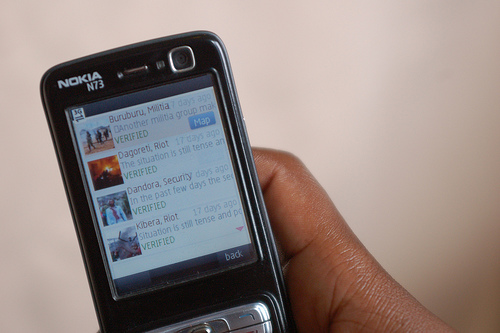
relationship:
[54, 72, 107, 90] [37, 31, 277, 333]
nokia written on cell phone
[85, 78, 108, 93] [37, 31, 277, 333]
n73 written on cell phone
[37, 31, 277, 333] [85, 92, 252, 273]
cell phone has a screen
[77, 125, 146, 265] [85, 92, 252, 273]
pictures are on screen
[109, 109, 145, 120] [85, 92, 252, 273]
buruburu written on screen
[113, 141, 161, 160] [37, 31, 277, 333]
dagoreti written on cell phone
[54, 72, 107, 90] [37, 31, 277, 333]
nokia n73 written on cell phone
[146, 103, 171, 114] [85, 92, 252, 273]
militia written on screen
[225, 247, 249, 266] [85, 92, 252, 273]
word written on screen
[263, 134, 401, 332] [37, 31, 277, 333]
person holding cell phone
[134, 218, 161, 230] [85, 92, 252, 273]
kibera written on screen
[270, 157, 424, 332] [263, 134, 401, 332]
hand of a person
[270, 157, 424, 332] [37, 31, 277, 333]
hand holding cell phone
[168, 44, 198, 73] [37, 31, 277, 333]
camera part of cell phone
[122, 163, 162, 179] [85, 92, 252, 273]
word written on screen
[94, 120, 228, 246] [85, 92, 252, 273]
news feed on screen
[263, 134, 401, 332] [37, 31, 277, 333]
person carrying cell phone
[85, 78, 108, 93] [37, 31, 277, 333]
n73 in on top of cell phone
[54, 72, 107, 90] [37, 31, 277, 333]
nokia on top of cell phone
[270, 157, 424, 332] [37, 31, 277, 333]
hand picking cell phone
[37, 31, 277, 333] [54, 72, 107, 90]
cell phone made by nokia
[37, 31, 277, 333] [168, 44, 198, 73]
cell phone contains a camera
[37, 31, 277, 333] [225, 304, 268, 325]
cell phone has a button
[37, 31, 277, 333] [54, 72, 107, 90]
cell phone produced by nokia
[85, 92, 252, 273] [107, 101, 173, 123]
screen contains name